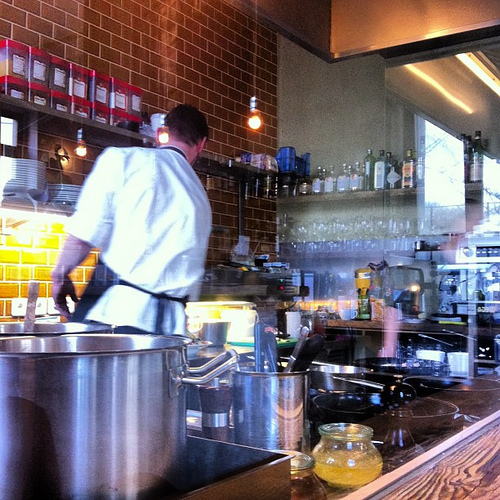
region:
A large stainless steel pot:
[11, 313, 191, 488]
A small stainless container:
[203, 312, 313, 439]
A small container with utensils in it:
[236, 317, 311, 454]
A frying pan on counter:
[322, 373, 376, 419]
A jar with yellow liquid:
[316, 421, 387, 484]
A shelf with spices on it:
[10, 34, 131, 126]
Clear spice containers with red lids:
[5, 34, 150, 114]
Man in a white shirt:
[93, 107, 221, 323]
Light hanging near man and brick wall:
[235, 19, 272, 140]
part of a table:
[467, 398, 482, 418]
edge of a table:
[389, 483, 394, 492]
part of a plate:
[408, 370, 420, 390]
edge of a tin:
[262, 413, 264, 418]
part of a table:
[276, 454, 279, 463]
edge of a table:
[448, 385, 455, 409]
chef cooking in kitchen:
[33, 85, 233, 337]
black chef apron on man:
[70, 260, 125, 314]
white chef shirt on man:
[61, 143, 216, 343]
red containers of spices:
[0, 45, 130, 108]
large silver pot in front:
[0, 302, 261, 451]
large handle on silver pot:
[171, 342, 246, 394]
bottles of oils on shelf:
[298, 153, 416, 197]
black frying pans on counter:
[310, 349, 410, 425]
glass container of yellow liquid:
[314, 409, 397, 479]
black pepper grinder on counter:
[382, 364, 417, 468]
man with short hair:
[156, 106, 207, 158]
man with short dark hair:
[155, 100, 227, 162]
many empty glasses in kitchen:
[286, 214, 425, 249]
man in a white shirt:
[102, 98, 211, 283]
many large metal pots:
[6, 298, 304, 495]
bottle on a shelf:
[363, 148, 409, 190]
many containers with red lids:
[9, 36, 134, 123]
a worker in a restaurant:
[25, 19, 350, 359]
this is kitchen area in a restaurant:
[30, 95, 402, 420]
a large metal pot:
[6, 324, 216, 491]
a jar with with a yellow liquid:
[303, 422, 382, 489]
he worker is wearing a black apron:
[51, 100, 233, 323]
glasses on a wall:
[276, 205, 441, 256]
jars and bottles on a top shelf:
[268, 137, 425, 197]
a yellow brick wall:
[4, 220, 99, 294]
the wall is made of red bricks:
[45, 8, 275, 75]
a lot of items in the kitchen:
[238, 226, 499, 453]